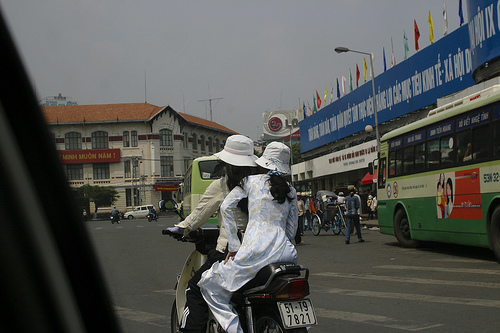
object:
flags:
[302, 0, 463, 119]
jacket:
[174, 174, 248, 254]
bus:
[377, 77, 500, 260]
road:
[84, 215, 500, 333]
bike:
[160, 224, 318, 333]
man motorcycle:
[111, 207, 119, 220]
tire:
[394, 208, 422, 247]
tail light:
[276, 279, 309, 299]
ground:
[85, 214, 500, 332]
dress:
[209, 174, 298, 292]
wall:
[45, 124, 158, 212]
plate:
[277, 298, 318, 329]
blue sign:
[299, 2, 500, 154]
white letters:
[309, 0, 500, 142]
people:
[167, 135, 260, 333]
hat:
[214, 134, 260, 167]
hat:
[256, 141, 291, 174]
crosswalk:
[113, 258, 500, 333]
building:
[291, 0, 500, 214]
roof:
[41, 101, 242, 134]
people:
[199, 141, 298, 333]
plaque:
[56, 148, 120, 163]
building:
[41, 102, 248, 213]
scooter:
[110, 213, 120, 224]